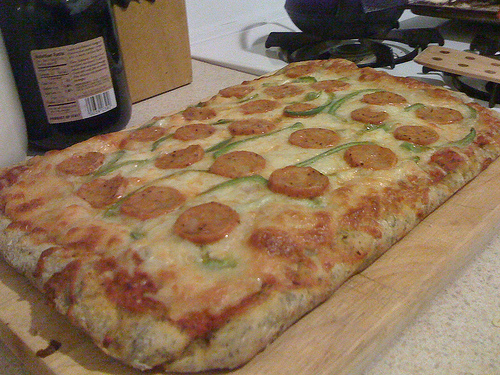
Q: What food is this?
A: Pizza.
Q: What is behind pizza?
A: Stove.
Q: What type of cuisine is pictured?
A: Italian.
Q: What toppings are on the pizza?
A: Pepperoni and peppers.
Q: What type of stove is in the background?
A: Gas.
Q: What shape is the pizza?
A: Rectangle.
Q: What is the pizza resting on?
A: Cutting board.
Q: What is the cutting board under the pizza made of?
A: Wood.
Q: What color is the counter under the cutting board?
A: Beige.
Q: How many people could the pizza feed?
A: Six.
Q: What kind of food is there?
A: Pizza.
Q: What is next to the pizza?
A: Bottle.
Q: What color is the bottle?
A: Brown.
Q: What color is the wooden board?
A: Tan.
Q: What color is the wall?
A: White.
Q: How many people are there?
A: None.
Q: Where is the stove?
A: Next to pizza.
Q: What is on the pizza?
A: An assortment of toppings.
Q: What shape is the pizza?
A: Rectangle.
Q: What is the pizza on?
A: Wooden platter.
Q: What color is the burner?
A: Black.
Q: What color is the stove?
A: White.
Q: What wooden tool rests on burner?
A: Spatula.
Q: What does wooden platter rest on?
A: Kitchen counter.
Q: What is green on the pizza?
A: Pepper.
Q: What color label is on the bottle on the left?
A: Tan.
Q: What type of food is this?
A: A pizza.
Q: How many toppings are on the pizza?
A: 3.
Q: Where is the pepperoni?
A: On the pizza.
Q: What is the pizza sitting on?
A: A board on the counter.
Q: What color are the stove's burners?
A: Black.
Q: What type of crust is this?
A: Thick.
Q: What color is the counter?
A: Light brown.